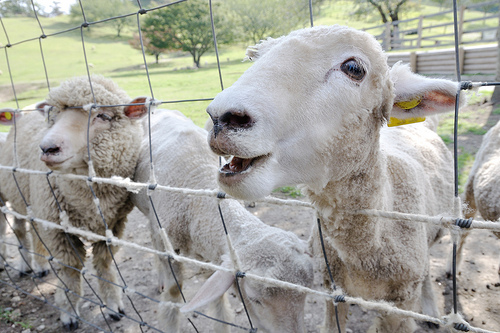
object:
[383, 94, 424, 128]
tag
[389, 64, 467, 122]
sheep's ear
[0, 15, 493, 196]
field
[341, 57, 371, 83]
eye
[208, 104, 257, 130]
nose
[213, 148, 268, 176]
mouth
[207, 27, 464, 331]
sheep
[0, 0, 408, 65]
trees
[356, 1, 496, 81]
fence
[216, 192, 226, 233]
line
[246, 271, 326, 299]
covering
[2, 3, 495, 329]
wire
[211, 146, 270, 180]
mouth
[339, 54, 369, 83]
eyes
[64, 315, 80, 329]
feet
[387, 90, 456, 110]
inside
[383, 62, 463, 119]
ears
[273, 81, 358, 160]
wool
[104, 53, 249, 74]
shadow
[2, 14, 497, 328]
ground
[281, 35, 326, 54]
bump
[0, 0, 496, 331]
pen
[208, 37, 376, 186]
face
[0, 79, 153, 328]
sheep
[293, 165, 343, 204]
sheep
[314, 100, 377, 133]
black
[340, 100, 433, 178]
tag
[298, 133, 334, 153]
white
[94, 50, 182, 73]
trees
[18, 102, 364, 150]
background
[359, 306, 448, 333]
fence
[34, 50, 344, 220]
two sheep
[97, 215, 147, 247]
camera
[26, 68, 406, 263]
sheep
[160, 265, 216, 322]
fence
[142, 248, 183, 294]
fence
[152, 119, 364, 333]
sheared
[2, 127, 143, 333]
sheared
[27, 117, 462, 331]
animals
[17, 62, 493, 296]
animals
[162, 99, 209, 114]
pen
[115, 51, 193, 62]
trees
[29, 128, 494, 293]
background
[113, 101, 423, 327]
fence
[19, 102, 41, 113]
animals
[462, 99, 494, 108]
timber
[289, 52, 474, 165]
timber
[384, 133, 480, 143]
timber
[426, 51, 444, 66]
timber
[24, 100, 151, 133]
distance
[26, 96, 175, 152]
distance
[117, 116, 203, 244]
distance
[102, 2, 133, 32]
tree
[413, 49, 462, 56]
wooden timber